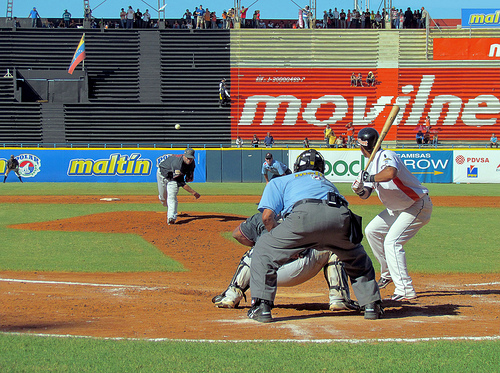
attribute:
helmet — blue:
[358, 125, 385, 150]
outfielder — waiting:
[9, 150, 32, 186]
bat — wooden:
[364, 105, 401, 170]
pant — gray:
[245, 202, 381, 307]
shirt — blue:
[239, 7, 248, 20]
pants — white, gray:
[359, 193, 429, 299]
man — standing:
[351, 99, 434, 311]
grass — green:
[46, 230, 152, 268]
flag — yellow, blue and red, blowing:
[68, 34, 87, 74]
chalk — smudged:
[211, 301, 335, 342]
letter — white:
[237, 89, 299, 127]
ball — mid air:
[174, 121, 182, 131]